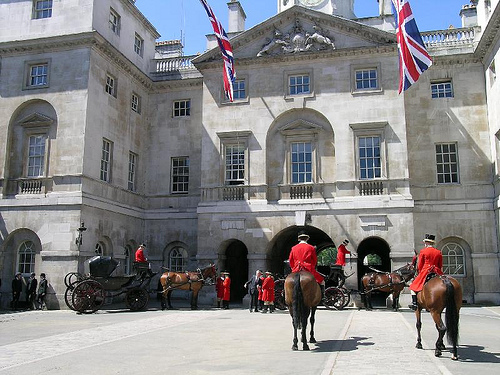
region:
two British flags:
[187, 1, 463, 116]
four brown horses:
[155, 266, 470, 351]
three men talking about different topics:
[4, 261, 57, 333]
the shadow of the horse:
[292, 291, 388, 366]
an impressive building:
[3, 28, 498, 238]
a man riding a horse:
[278, 219, 340, 356]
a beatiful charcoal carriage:
[63, 253, 153, 313]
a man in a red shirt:
[400, 217, 452, 295]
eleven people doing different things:
[3, 225, 489, 363]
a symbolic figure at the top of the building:
[256, 12, 344, 71]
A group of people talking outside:
[2, 221, 62, 336]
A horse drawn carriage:
[50, 225, 228, 319]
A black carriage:
[55, 243, 162, 317]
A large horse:
[147, 258, 235, 316]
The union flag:
[368, 3, 468, 95]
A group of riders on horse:
[50, 218, 497, 373]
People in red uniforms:
[206, 254, 286, 316]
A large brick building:
[1, 0, 498, 337]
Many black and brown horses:
[156, 259, 498, 368]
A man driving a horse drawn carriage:
[51, 213, 229, 320]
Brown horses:
[71, 223, 498, 368]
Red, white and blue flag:
[190, 0, 454, 97]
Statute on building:
[253, 7, 340, 62]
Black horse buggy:
[70, 234, 161, 324]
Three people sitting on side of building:
[8, 261, 54, 321]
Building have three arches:
[196, 204, 408, 311]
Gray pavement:
[90, 325, 228, 370]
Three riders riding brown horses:
[289, 227, 464, 357]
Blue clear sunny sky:
[147, 4, 216, 39]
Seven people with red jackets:
[82, 234, 467, 367]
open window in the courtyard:
[209, 175, 251, 200]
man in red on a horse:
[273, 213, 330, 365]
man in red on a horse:
[407, 229, 467, 371]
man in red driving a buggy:
[52, 215, 157, 324]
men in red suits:
[212, 260, 242, 320]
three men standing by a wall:
[0, 253, 60, 318]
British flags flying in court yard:
[167, 3, 263, 104]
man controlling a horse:
[325, 218, 407, 325]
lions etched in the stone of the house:
[260, 11, 355, 71]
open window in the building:
[161, 151, 201, 226]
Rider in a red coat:
[278, 221, 351, 291]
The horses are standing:
[278, 222, 490, 359]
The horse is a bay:
[397, 232, 462, 372]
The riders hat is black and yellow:
[272, 221, 321, 245]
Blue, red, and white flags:
[176, 6, 441, 105]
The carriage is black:
[63, 242, 233, 322]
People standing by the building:
[8, 265, 78, 317]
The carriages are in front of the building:
[57, 233, 428, 324]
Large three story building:
[26, 3, 488, 300]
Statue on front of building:
[248, 19, 349, 66]